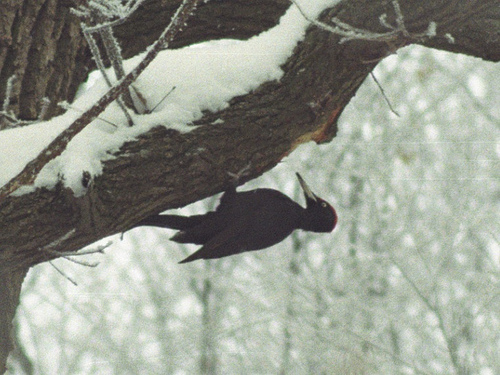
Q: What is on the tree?
A: Bird and snow.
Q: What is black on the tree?
A: Bird.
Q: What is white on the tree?
A: Snow.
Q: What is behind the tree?
A: Trees.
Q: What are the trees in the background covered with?
A: Snow.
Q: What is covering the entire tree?
A: Bark.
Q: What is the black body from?
A: Bird.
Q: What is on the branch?
A: Bird.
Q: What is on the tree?
A: Woodpecker.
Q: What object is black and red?
A: Woodpecker.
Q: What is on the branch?
A: Snow.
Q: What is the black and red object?
A: Bird.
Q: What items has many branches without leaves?
A: Tree.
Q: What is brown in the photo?
A: Branch.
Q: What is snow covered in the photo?
A: Branch.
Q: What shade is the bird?
A: The bird is black.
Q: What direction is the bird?
A: The bird is upside down.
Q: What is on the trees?
A: Snow.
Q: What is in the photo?
A: A bird.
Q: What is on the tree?
A: Bark.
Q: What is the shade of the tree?
A: Brown.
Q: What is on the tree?
A: Wood.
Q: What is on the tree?
A: Snow.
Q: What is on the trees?
A: Snow on the branches.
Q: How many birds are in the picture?
A: One.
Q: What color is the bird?
A: Black.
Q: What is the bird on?
A: A tree.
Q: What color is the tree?
A: Brown.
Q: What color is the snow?
A: White.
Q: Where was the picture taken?
A: In the forest.